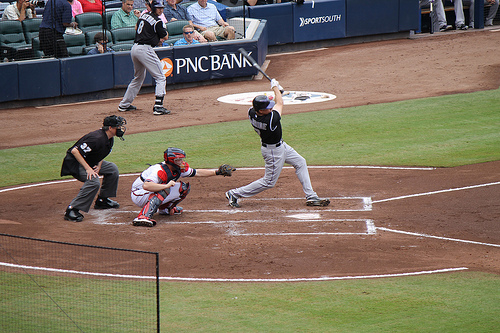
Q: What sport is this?
A: Baseball.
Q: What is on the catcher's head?
A: Helmet.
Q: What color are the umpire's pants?
A: Gray.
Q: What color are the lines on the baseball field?
A: White.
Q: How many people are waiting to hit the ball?
A: 1.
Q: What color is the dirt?
A: Brown.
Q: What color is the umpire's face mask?
A: Black.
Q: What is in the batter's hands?
A: Bat.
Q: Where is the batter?
A: Home Plate.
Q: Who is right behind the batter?
A: The catcher.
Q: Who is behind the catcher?
A: The umpire.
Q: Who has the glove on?
A: The catcher.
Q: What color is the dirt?
A: Brown.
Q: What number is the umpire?
A: Thirty Seven.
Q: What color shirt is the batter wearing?
A: Black.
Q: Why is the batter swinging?
A: To hit the ball.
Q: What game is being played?
A: Baseball.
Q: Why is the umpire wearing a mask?
A: To protect his face.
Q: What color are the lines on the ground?
A: White.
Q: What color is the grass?
A: Green.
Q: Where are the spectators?
A: In the stands.